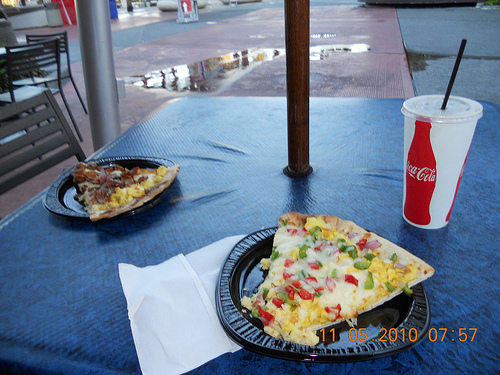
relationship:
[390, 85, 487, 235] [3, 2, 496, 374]
drink on table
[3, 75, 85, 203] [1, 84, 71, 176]
chair has back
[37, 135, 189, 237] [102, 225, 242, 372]
plate on napkin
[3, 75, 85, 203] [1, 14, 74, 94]
chair on background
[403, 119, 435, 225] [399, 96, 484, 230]
coca-cola logo on cup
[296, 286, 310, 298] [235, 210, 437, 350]
tomato on pizza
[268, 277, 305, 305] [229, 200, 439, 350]
tomato on pizza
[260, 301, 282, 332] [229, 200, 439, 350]
tomato on pizza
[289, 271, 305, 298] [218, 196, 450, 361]
tomato on pizza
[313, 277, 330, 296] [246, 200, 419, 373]
tomato on pizza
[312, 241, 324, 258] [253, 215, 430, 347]
tomato on pizza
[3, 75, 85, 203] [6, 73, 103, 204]
chair has slats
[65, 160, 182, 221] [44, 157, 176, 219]
pizza on plate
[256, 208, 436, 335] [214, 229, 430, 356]
pizza on plate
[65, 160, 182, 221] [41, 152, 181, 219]
pizza on plate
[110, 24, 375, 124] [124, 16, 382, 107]
water on ground